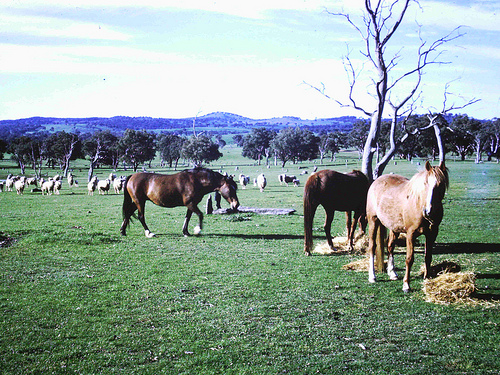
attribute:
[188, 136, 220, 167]
tree — green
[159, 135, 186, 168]
tree — green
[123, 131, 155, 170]
tree — green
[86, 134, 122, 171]
tree — green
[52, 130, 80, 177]
tree — green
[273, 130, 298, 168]
tree — green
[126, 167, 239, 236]
horse — walking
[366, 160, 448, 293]
horse — brown, standing, light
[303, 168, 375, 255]
horse — brown, dark